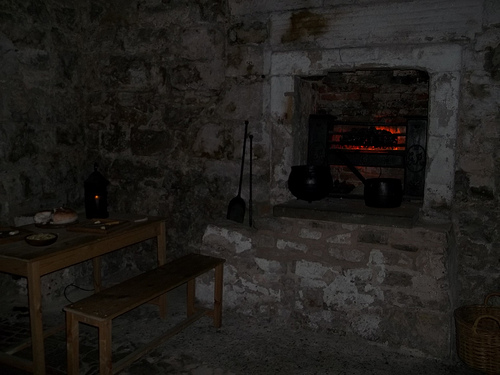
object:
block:
[131, 126, 172, 155]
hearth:
[198, 200, 457, 353]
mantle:
[260, 40, 467, 215]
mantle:
[185, 140, 454, 355]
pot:
[347, 165, 403, 207]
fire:
[331, 125, 405, 150]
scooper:
[226, 120, 250, 224]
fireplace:
[268, 44, 462, 229]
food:
[27, 233, 56, 240]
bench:
[59, 252, 227, 375]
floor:
[4, 286, 457, 373]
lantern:
[84, 163, 110, 219]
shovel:
[226, 120, 250, 224]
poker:
[248, 134, 254, 227]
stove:
[300, 106, 420, 209]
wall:
[200, 207, 480, 366]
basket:
[453, 292, 500, 372]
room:
[4, 1, 493, 370]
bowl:
[24, 232, 58, 247]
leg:
[25, 277, 44, 373]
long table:
[0, 211, 166, 374]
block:
[195, 221, 455, 361]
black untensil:
[226, 120, 254, 228]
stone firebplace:
[252, 31, 472, 362]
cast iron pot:
[288, 165, 334, 205]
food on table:
[27, 232, 56, 240]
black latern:
[83, 162, 109, 219]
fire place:
[331, 125, 406, 151]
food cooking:
[339, 127, 399, 146]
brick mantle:
[269, 44, 462, 229]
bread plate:
[34, 207, 79, 224]